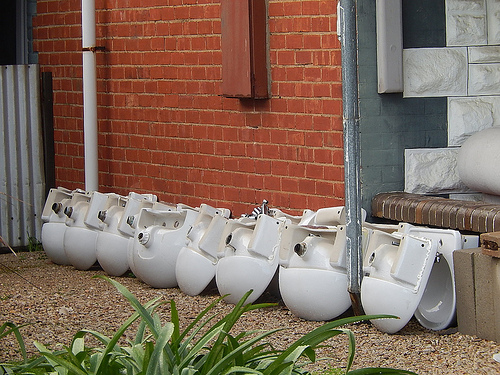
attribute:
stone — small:
[46, 293, 77, 318]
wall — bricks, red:
[127, 51, 222, 144]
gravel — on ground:
[4, 247, 498, 373]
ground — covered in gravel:
[3, 231, 498, 373]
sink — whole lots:
[360, 228, 436, 335]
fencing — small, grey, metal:
[2, 61, 49, 248]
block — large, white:
[400, 52, 471, 97]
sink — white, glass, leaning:
[299, 223, 346, 306]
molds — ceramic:
[410, 52, 466, 99]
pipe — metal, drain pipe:
[341, 2, 360, 304]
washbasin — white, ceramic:
[288, 197, 365, 330]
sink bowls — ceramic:
[36, 129, 463, 331]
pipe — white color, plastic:
[331, 0, 376, 325]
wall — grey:
[355, 0, 448, 222]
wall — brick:
[237, 85, 294, 142]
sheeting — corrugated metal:
[6, 43, 71, 303]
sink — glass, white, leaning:
[362, 221, 434, 327]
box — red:
[209, 24, 284, 114]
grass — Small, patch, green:
[0, 289, 419, 371]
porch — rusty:
[372, 190, 498, 232]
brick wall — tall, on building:
[31, 2, 347, 216]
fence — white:
[11, 58, 71, 193]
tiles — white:
[394, 20, 495, 155]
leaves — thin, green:
[7, 274, 437, 374]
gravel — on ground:
[360, 335, 499, 370]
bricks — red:
[156, 104, 300, 163]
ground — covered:
[15, 286, 123, 329]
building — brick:
[48, 26, 335, 175]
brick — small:
[404, 49, 477, 95]